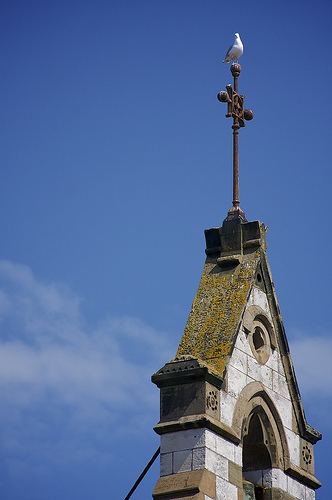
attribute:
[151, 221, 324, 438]
roof — orange, triangular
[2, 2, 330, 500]
sky — blue, cloudless, clear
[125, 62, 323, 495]
building — mortar, grey, stone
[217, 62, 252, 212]
weather vane — rusty, metal, cross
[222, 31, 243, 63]
bird — white, pigeon, small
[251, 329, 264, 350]
window — circular, decorative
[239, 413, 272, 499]
window — small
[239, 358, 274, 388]
stones — white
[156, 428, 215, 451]
stones — white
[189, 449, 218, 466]
stones — white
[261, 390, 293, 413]
stones — white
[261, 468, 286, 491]
stones — white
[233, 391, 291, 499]
arch — concrete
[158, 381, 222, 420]
block — decorated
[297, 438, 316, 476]
block — decorated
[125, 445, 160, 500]
brace — black, metal